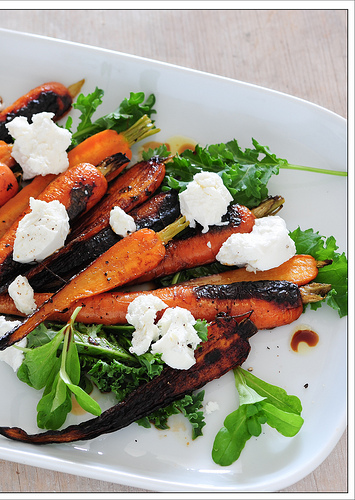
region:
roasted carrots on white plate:
[1, 65, 354, 486]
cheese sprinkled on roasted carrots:
[3, 82, 348, 476]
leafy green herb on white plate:
[17, 304, 92, 429]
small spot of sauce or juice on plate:
[291, 319, 322, 355]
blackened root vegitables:
[0, 69, 352, 483]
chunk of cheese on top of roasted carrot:
[176, 160, 259, 258]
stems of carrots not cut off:
[18, 64, 164, 175]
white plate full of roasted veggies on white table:
[0, 9, 354, 491]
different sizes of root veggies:
[0, 16, 343, 490]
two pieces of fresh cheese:
[98, 279, 237, 372]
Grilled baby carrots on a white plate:
[74, 205, 303, 436]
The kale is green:
[96, 342, 129, 385]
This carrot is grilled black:
[66, 250, 90, 265]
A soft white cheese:
[231, 216, 291, 272]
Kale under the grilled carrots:
[183, 153, 271, 226]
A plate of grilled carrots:
[40, 90, 151, 234]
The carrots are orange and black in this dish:
[160, 255, 263, 312]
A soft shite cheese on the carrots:
[225, 220, 304, 286]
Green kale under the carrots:
[117, 358, 212, 438]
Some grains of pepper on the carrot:
[86, 244, 123, 305]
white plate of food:
[14, 47, 343, 405]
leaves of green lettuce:
[166, 139, 279, 197]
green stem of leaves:
[279, 159, 348, 179]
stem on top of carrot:
[117, 115, 158, 146]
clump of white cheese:
[9, 111, 71, 177]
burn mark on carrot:
[67, 178, 95, 214]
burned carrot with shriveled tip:
[3, 320, 249, 445]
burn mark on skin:
[195, 278, 298, 306]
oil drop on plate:
[291, 324, 317, 355]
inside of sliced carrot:
[183, 259, 314, 285]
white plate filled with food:
[21, 55, 317, 471]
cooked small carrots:
[9, 253, 306, 333]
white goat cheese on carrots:
[123, 170, 301, 362]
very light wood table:
[253, 22, 321, 79]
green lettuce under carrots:
[37, 317, 148, 405]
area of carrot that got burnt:
[196, 275, 295, 301]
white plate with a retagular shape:
[96, 93, 332, 486]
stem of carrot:
[115, 115, 162, 145]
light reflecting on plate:
[169, 462, 249, 478]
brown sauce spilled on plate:
[277, 310, 332, 358]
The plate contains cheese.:
[176, 170, 233, 230]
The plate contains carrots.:
[195, 280, 330, 326]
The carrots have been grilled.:
[66, 179, 96, 213]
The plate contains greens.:
[16, 324, 76, 427]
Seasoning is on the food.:
[19, 217, 53, 245]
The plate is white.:
[176, 91, 267, 128]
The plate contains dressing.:
[291, 329, 317, 351]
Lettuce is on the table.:
[83, 326, 128, 378]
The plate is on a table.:
[186, 11, 345, 64]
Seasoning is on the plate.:
[264, 344, 282, 357]